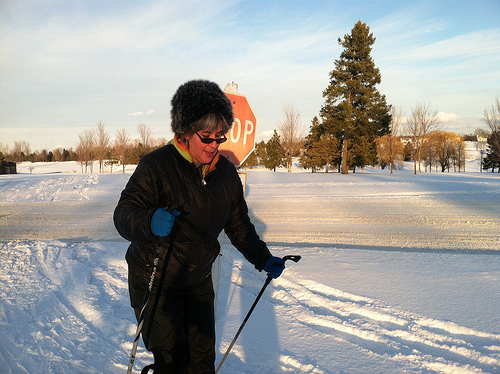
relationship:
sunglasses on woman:
[214, 131, 275, 156] [92, 73, 314, 351]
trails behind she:
[3, 240, 499, 370] [112, 79, 285, 374]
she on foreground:
[112, 79, 285, 374] [5, 128, 495, 176]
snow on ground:
[216, 177, 498, 372] [5, 168, 495, 372]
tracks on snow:
[298, 275, 457, 372] [335, 239, 404, 291]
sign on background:
[222, 94, 256, 167] [1, 130, 495, 179]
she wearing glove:
[112, 79, 285, 374] [152, 203, 184, 241]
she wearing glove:
[112, 79, 285, 374] [263, 254, 287, 279]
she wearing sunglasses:
[112, 79, 285, 374] [199, 133, 225, 145]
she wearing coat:
[112, 79, 285, 374] [111, 144, 271, 311]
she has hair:
[112, 79, 285, 374] [171, 79, 234, 144]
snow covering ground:
[216, 177, 498, 372] [233, 170, 498, 359]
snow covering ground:
[0, 172, 126, 369] [0, 176, 128, 371]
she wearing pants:
[115, 79, 287, 371] [122, 257, 217, 372]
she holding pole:
[112, 79, 285, 374] [215, 253, 302, 372]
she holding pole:
[112, 79, 285, 374] [127, 239, 165, 372]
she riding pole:
[112, 79, 285, 374] [215, 255, 302, 372]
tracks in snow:
[3, 242, 497, 371] [1, 139, 497, 371]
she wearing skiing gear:
[112, 79, 285, 374] [112, 136, 283, 372]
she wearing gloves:
[112, 79, 285, 374] [142, 190, 179, 240]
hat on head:
[163, 73, 238, 123] [152, 70, 240, 170]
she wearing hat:
[112, 79, 285, 374] [163, 73, 238, 123]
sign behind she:
[222, 94, 256, 167] [112, 79, 285, 374]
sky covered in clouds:
[7, 6, 479, 143] [11, 4, 485, 136]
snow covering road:
[216, 177, 498, 372] [2, 188, 487, 263]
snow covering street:
[216, 177, 498, 372] [6, 182, 488, 252]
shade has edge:
[203, 235, 323, 372] [291, 247, 301, 264]